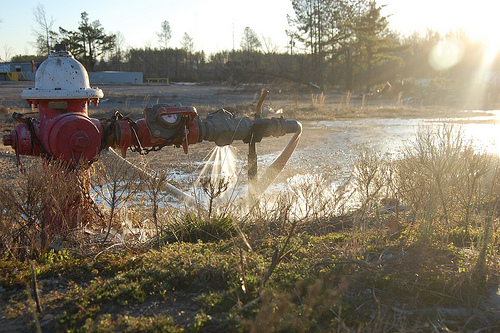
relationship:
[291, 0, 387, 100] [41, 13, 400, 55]
group in distance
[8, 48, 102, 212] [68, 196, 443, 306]
hydrant in field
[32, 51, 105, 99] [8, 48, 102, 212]
cap on hydrant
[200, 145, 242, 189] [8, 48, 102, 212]
water from hydrant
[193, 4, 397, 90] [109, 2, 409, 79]
trees in background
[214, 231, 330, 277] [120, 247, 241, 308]
branches in grass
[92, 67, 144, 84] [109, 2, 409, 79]
building in background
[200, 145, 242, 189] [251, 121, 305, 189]
water hose fire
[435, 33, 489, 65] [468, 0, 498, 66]
glare of light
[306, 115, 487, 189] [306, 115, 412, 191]
large water large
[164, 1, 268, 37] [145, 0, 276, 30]
bright blue skies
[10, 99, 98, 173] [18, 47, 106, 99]
red hydrant cap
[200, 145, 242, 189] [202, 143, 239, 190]
water spraying out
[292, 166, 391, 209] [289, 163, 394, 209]
bare leafless bushes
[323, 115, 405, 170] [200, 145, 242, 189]
reservoir of water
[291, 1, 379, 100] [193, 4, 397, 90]
group of trees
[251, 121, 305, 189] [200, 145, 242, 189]
fire connecting water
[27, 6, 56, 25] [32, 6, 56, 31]
bare leafless tree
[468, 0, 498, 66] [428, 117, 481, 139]
light reflecting water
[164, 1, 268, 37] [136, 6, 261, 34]
bright blue sky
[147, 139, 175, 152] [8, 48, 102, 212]
chain on hydrant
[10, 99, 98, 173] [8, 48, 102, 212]
red fire hydrant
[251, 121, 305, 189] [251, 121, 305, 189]
fire hose fire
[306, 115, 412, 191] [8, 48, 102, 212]
large behind hydrant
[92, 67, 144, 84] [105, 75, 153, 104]
building in clearing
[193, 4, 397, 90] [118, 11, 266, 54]
trees on horizon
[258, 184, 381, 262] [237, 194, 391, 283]
weeds on bank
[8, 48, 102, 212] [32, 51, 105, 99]
hydrant white cap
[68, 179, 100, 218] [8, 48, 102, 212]
chains on hydrant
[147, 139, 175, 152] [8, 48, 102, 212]
chain connection hydrant